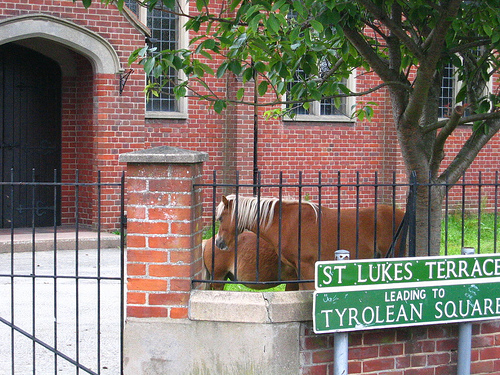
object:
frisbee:
[387, 73, 439, 189]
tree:
[70, 2, 499, 260]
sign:
[305, 252, 499, 333]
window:
[145, 0, 186, 117]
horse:
[212, 191, 415, 288]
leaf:
[213, 99, 227, 114]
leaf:
[234, 85, 247, 99]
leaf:
[257, 78, 269, 97]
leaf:
[216, 60, 230, 80]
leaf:
[229, 59, 241, 76]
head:
[214, 192, 245, 252]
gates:
[9, 160, 129, 372]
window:
[440, 57, 455, 118]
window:
[322, 41, 344, 113]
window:
[286, 12, 312, 113]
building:
[0, 1, 498, 231]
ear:
[221, 192, 233, 209]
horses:
[200, 224, 300, 292]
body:
[282, 209, 424, 265]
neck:
[235, 199, 304, 257]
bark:
[392, 115, 444, 259]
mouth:
[214, 237, 231, 252]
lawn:
[192, 209, 495, 293]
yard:
[194, 205, 495, 293]